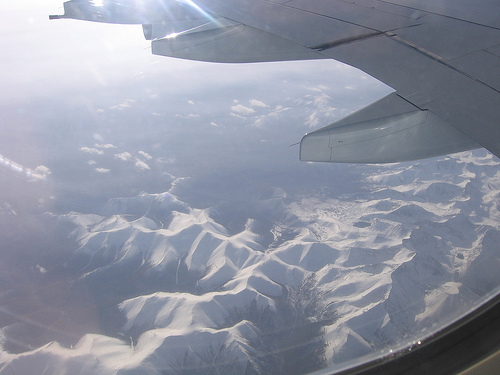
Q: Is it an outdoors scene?
A: Yes, it is outdoors.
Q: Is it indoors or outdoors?
A: It is outdoors.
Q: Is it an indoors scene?
A: No, it is outdoors.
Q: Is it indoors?
A: No, it is outdoors.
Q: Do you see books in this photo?
A: No, there are no books.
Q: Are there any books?
A: No, there are no books.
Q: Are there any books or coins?
A: No, there are no books or coins.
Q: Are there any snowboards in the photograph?
A: No, there are no snowboards.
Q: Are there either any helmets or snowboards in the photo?
A: No, there are no snowboards or helmets.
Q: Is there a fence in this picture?
A: No, there are no fences.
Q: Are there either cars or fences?
A: No, there are no fences or cars.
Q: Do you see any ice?
A: Yes, there is ice.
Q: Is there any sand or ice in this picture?
A: Yes, there is ice.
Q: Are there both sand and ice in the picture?
A: No, there is ice but no sand.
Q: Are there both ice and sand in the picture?
A: No, there is ice but no sand.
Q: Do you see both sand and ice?
A: No, there is ice but no sand.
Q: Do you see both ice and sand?
A: No, there is ice but no sand.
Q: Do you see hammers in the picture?
A: No, there are no hammers.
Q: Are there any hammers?
A: No, there are no hammers.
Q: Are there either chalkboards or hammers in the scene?
A: No, there are no hammers or chalkboards.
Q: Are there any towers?
A: No, there are no towers.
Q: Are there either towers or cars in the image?
A: No, there are no towers or cars.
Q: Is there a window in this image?
A: Yes, there is a window.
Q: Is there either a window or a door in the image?
A: Yes, there is a window.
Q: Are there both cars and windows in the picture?
A: No, there is a window but no cars.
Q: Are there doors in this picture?
A: No, there are no doors.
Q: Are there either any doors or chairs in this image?
A: No, there are no doors or chairs.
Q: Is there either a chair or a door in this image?
A: No, there are no doors or chairs.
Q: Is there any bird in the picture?
A: No, there are no birds.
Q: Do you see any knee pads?
A: No, there are no knee pads.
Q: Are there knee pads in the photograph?
A: No, there are no knee pads.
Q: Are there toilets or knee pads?
A: No, there are no knee pads or toilets.